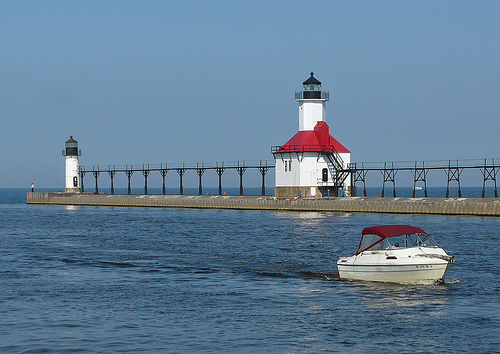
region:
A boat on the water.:
[333, 210, 458, 287]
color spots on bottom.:
[340, 265, 427, 281]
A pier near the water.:
[74, 158, 266, 192]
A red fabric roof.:
[353, 216, 430, 236]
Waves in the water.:
[243, 257, 331, 285]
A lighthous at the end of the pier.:
[59, 128, 89, 202]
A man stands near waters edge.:
[25, 181, 38, 196]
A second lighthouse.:
[292, 70, 331, 102]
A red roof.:
[273, 123, 356, 155]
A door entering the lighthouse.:
[319, 161, 332, 183]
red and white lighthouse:
[245, 59, 386, 216]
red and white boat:
[326, 185, 474, 294]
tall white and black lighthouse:
[46, 115, 124, 229]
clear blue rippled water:
[15, 196, 449, 335]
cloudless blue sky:
[36, 18, 470, 194]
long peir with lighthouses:
[40, 137, 480, 259]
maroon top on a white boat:
[350, 207, 451, 251]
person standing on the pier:
[25, 176, 47, 206]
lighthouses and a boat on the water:
[16, 46, 471, 309]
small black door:
[319, 165, 336, 186]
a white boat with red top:
[335, 224, 450, 284]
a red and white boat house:
[273, 71, 351, 197]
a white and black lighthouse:
[59, 136, 84, 193]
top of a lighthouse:
[294, 74, 329, 101]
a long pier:
[25, 163, 497, 212]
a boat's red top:
[356, 223, 433, 235]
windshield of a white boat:
[387, 232, 436, 247]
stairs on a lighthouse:
[327, 152, 347, 192]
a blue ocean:
[2, 186, 499, 351]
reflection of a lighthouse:
[270, 208, 350, 235]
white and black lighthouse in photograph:
[47, 135, 101, 212]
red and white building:
[272, 52, 354, 199]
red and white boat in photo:
[352, 208, 463, 319]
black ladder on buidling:
[310, 125, 355, 200]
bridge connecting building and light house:
[61, 154, 465, 209]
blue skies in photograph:
[24, 24, 341, 182]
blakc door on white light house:
[51, 164, 92, 194]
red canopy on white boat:
[351, 210, 452, 272]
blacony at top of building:
[282, 72, 332, 102]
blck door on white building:
[311, 157, 342, 191]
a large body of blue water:
[5, 167, 498, 352]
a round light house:
[57, 120, 89, 200]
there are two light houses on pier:
[51, 62, 363, 219]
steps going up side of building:
[311, 135, 355, 197]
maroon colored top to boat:
[354, 203, 435, 260]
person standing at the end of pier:
[22, 177, 40, 197]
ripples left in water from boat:
[18, 236, 351, 293]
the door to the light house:
[72, 172, 78, 189]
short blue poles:
[294, 187, 346, 199]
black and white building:
[58, 127, 86, 201]